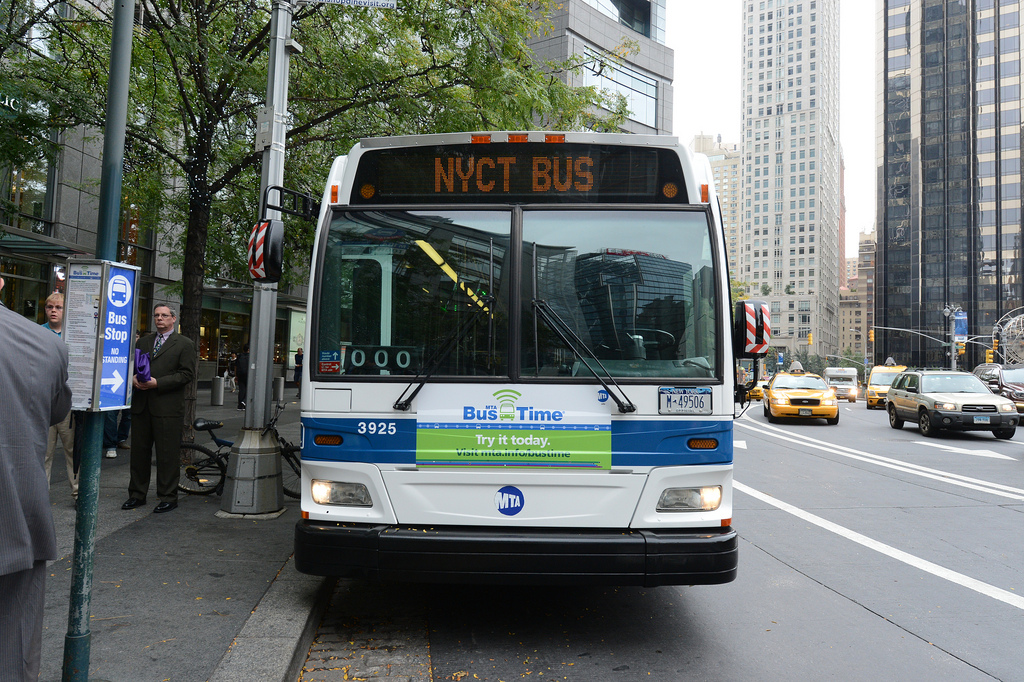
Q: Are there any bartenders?
A: No, there are no bartenders.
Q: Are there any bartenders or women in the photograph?
A: No, there are no bartenders or women.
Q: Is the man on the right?
A: No, the man is on the left of the image.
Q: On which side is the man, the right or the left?
A: The man is on the left of the image.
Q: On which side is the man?
A: The man is on the left of the image.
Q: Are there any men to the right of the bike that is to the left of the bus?
A: No, the man is to the left of the bike.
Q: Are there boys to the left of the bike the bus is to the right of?
A: No, there is a man to the left of the bike.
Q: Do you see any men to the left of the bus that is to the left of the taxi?
A: Yes, there is a man to the left of the bus.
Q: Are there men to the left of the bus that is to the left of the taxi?
A: Yes, there is a man to the left of the bus.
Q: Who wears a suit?
A: The man wears a suit.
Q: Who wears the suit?
A: The man wears a suit.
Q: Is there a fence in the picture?
A: No, there are no fences.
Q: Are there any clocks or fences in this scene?
A: No, there are no fences or clocks.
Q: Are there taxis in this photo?
A: Yes, there is a taxi.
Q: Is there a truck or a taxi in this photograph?
A: Yes, there is a taxi.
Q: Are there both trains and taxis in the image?
A: No, there is a taxi but no trains.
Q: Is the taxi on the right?
A: Yes, the taxi is on the right of the image.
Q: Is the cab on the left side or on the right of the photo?
A: The cab is on the right of the image.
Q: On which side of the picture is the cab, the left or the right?
A: The cab is on the right of the image.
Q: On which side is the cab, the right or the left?
A: The cab is on the right of the image.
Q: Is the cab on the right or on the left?
A: The cab is on the right of the image.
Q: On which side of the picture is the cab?
A: The cab is on the right of the image.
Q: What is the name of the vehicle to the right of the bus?
A: The vehicle is a taxi.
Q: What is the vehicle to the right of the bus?
A: The vehicle is a taxi.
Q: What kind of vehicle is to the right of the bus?
A: The vehicle is a taxi.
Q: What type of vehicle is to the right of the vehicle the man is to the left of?
A: The vehicle is a taxi.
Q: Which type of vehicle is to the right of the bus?
A: The vehicle is a taxi.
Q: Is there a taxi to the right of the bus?
A: Yes, there is a taxi to the right of the bus.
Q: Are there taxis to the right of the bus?
A: Yes, there is a taxi to the right of the bus.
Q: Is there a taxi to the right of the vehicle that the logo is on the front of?
A: Yes, there is a taxi to the right of the bus.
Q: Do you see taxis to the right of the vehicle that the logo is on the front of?
A: Yes, there is a taxi to the right of the bus.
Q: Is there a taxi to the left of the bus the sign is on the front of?
A: No, the taxi is to the right of the bus.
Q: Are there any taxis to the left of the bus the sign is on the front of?
A: No, the taxi is to the right of the bus.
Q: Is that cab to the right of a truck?
A: No, the cab is to the right of the bus.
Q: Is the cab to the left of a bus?
A: No, the cab is to the right of a bus.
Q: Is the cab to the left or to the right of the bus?
A: The cab is to the right of the bus.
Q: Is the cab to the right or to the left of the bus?
A: The cab is to the right of the bus.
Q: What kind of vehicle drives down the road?
A: The vehicle is a taxi.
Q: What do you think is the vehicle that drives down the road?
A: The vehicle is a taxi.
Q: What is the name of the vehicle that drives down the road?
A: The vehicle is a taxi.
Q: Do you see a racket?
A: No, there are no rackets.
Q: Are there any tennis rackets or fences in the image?
A: No, there are no tennis rackets or fences.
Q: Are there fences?
A: No, there are no fences.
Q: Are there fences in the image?
A: No, there are no fences.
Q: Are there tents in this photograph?
A: No, there are no tents.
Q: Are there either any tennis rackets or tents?
A: No, there are no tents or tennis rackets.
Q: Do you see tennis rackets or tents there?
A: No, there are no tents or tennis rackets.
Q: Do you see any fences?
A: No, there are no fences.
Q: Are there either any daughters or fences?
A: No, there are no fences or daughters.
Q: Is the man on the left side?
A: Yes, the man is on the left of the image.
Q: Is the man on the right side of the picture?
A: No, the man is on the left of the image.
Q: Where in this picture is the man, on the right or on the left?
A: The man is on the left of the image.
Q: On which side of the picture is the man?
A: The man is on the left of the image.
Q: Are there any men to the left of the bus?
A: Yes, there is a man to the left of the bus.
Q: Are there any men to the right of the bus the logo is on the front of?
A: No, the man is to the left of the bus.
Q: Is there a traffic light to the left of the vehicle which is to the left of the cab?
A: No, there is a man to the left of the bus.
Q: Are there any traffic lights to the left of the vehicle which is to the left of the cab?
A: No, there is a man to the left of the bus.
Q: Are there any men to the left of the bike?
A: Yes, there is a man to the left of the bike.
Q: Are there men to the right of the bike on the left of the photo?
A: No, the man is to the left of the bike.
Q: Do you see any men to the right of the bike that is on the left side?
A: No, the man is to the left of the bike.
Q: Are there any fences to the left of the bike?
A: No, there is a man to the left of the bike.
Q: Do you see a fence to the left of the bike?
A: No, there is a man to the left of the bike.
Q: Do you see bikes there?
A: Yes, there is a bike.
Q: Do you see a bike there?
A: Yes, there is a bike.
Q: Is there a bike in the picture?
A: Yes, there is a bike.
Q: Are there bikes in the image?
A: Yes, there is a bike.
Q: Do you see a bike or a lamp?
A: Yes, there is a bike.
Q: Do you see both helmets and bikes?
A: No, there is a bike but no helmets.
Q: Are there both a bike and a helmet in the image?
A: No, there is a bike but no helmets.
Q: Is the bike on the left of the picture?
A: Yes, the bike is on the left of the image.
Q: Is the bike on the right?
A: No, the bike is on the left of the image.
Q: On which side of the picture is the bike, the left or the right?
A: The bike is on the left of the image.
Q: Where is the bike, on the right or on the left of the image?
A: The bike is on the left of the image.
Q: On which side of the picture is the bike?
A: The bike is on the left of the image.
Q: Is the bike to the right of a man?
A: Yes, the bike is to the right of a man.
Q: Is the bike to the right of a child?
A: No, the bike is to the right of a man.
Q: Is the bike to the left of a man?
A: No, the bike is to the right of a man.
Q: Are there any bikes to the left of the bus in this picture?
A: Yes, there is a bike to the left of the bus.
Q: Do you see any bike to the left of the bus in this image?
A: Yes, there is a bike to the left of the bus.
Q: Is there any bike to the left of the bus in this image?
A: Yes, there is a bike to the left of the bus.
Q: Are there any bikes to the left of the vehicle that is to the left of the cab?
A: Yes, there is a bike to the left of the bus.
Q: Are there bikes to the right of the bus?
A: No, the bike is to the left of the bus.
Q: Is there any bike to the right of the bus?
A: No, the bike is to the left of the bus.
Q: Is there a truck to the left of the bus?
A: No, there is a bike to the left of the bus.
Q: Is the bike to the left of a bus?
A: Yes, the bike is to the left of a bus.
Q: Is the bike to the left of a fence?
A: No, the bike is to the left of a bus.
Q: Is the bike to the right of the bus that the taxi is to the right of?
A: No, the bike is to the left of the bus.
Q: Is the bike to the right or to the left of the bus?
A: The bike is to the left of the bus.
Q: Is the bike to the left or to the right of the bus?
A: The bike is to the left of the bus.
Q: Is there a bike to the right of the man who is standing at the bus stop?
A: Yes, there is a bike to the right of the man.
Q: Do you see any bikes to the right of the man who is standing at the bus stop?
A: Yes, there is a bike to the right of the man.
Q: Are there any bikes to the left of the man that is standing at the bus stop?
A: No, the bike is to the right of the man.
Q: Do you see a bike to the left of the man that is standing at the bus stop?
A: No, the bike is to the right of the man.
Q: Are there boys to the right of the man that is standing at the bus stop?
A: No, there is a bike to the right of the man.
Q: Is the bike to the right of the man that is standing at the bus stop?
A: Yes, the bike is to the right of the man.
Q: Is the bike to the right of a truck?
A: No, the bike is to the right of the man.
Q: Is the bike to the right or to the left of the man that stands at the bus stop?
A: The bike is to the right of the man.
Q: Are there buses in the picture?
A: Yes, there is a bus.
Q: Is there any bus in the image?
A: Yes, there is a bus.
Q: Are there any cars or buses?
A: Yes, there is a bus.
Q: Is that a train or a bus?
A: That is a bus.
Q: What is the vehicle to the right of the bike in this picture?
A: The vehicle is a bus.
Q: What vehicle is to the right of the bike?
A: The vehicle is a bus.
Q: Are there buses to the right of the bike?
A: Yes, there is a bus to the right of the bike.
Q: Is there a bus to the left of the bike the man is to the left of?
A: No, the bus is to the right of the bike.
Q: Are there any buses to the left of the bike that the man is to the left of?
A: No, the bus is to the right of the bike.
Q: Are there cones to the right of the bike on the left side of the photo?
A: No, there is a bus to the right of the bike.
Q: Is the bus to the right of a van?
A: No, the bus is to the right of a bike.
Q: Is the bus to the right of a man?
A: Yes, the bus is to the right of a man.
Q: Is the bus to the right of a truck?
A: No, the bus is to the right of a man.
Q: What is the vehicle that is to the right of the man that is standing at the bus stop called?
A: The vehicle is a bus.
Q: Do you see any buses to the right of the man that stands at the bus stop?
A: Yes, there is a bus to the right of the man.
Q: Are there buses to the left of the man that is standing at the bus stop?
A: No, the bus is to the right of the man.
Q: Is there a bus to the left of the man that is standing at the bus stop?
A: No, the bus is to the right of the man.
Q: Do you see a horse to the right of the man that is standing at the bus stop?
A: No, there is a bus to the right of the man.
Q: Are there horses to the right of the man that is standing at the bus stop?
A: No, there is a bus to the right of the man.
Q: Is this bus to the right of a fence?
A: No, the bus is to the right of a man.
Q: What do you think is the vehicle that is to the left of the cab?
A: The vehicle is a bus.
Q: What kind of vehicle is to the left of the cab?
A: The vehicle is a bus.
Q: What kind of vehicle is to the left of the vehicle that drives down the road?
A: The vehicle is a bus.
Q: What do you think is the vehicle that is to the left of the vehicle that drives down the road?
A: The vehicle is a bus.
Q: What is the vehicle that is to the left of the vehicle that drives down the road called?
A: The vehicle is a bus.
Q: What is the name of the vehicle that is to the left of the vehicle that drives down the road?
A: The vehicle is a bus.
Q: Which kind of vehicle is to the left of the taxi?
A: The vehicle is a bus.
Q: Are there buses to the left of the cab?
A: Yes, there is a bus to the left of the cab.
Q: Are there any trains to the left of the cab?
A: No, there is a bus to the left of the cab.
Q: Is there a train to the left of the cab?
A: No, there is a bus to the left of the cab.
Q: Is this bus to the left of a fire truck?
A: No, the bus is to the left of a taxi.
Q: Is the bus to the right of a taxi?
A: No, the bus is to the left of a taxi.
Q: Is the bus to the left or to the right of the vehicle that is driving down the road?
A: The bus is to the left of the cab.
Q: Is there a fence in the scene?
A: No, there are no fences.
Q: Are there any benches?
A: No, there are no benches.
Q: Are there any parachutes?
A: No, there are no parachutes.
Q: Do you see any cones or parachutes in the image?
A: No, there are no parachutes or cones.